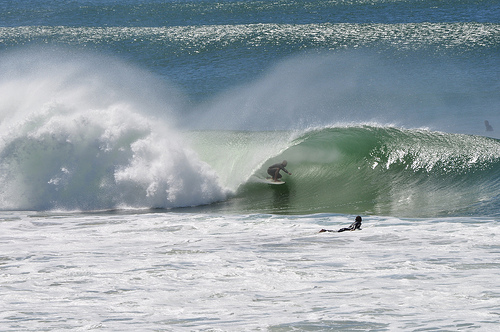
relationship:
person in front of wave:
[320, 214, 365, 233] [312, 82, 497, 207]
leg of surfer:
[271, 165, 279, 180] [271, 158, 290, 171]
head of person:
[348, 205, 370, 227] [320, 214, 365, 233]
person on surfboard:
[257, 156, 293, 183] [260, 176, 287, 186]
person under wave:
[257, 156, 293, 183] [163, 122, 489, 194]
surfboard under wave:
[260, 176, 287, 186] [163, 122, 489, 194]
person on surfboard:
[480, 115, 495, 133] [260, 176, 287, 186]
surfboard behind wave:
[260, 176, 287, 186] [2, 24, 493, 216]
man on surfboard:
[266, 158, 292, 179] [270, 179, 285, 185]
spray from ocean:
[38, 37, 175, 130] [80, 28, 427, 250]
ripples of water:
[413, 260, 444, 280] [0, 2, 497, 326]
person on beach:
[320, 214, 365, 233] [82, 109, 482, 295]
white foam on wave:
[59, 119, 179, 329] [0, 98, 497, 215]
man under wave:
[266, 158, 291, 183] [32, 80, 494, 222]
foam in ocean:
[0, 213, 498, 329] [1, 1, 497, 330]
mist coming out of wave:
[12, 46, 181, 121] [2, 109, 498, 219]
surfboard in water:
[264, 176, 287, 186] [7, 102, 497, 330]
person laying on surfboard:
[320, 214, 365, 233] [316, 228, 359, 235]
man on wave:
[266, 158, 291, 183] [2, 109, 498, 219]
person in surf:
[315, 215, 362, 237] [0, 207, 497, 330]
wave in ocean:
[23, 100, 458, 221] [7, 12, 456, 324]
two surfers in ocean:
[256, 115, 498, 248] [69, 39, 497, 287]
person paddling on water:
[323, 217, 372, 229] [0, 2, 497, 326]